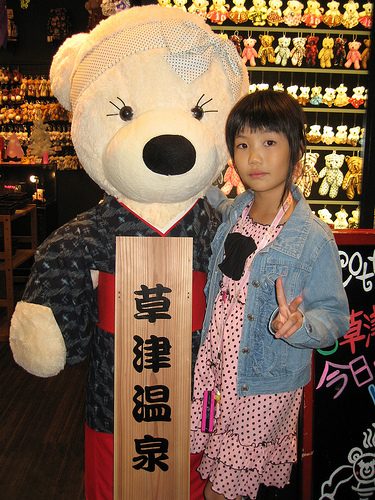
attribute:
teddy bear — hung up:
[340, 1, 358, 28]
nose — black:
[144, 136, 196, 173]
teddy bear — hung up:
[347, 127, 360, 147]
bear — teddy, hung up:
[9, 4, 254, 488]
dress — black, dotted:
[186, 186, 311, 499]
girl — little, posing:
[190, 90, 350, 498]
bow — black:
[216, 228, 261, 283]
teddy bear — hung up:
[239, 35, 259, 66]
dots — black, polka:
[261, 225, 265, 229]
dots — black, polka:
[230, 287, 234, 290]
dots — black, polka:
[245, 232, 248, 234]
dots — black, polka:
[223, 322, 228, 326]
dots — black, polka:
[209, 327, 214, 332]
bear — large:
[90, 41, 228, 213]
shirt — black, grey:
[51, 198, 254, 397]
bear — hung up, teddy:
[27, 37, 256, 335]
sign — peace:
[265, 275, 314, 367]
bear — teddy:
[257, 33, 276, 67]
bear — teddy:
[276, 28, 290, 72]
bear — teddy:
[321, 30, 335, 70]